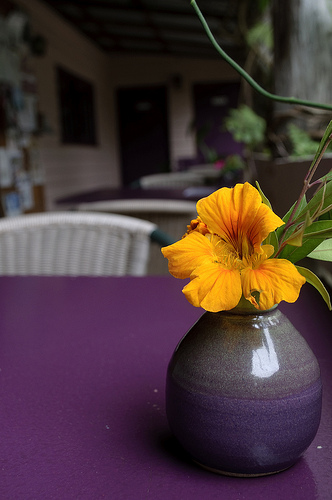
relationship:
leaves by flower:
[255, 119, 330, 311] [162, 180, 306, 309]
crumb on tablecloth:
[151, 386, 161, 394] [1, 268, 330, 497]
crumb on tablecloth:
[314, 442, 322, 449] [1, 268, 330, 497]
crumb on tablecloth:
[103, 423, 109, 430] [1, 268, 330, 497]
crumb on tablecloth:
[156, 406, 162, 411] [1, 268, 330, 497]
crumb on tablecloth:
[152, 399, 159, 409] [1, 268, 330, 497]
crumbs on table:
[151, 387, 159, 411] [10, 275, 165, 488]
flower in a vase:
[162, 180, 306, 309] [155, 312, 320, 475]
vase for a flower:
[162, 296, 327, 478] [162, 180, 306, 309]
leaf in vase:
[256, 171, 332, 266] [162, 296, 327, 478]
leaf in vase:
[280, 219, 330, 267] [162, 296, 327, 478]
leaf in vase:
[288, 262, 330, 311] [162, 296, 327, 478]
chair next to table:
[1, 207, 155, 274] [2, 271, 324, 499]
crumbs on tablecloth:
[151, 387, 164, 421] [1, 268, 330, 497]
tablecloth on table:
[55, 184, 210, 215] [64, 187, 213, 208]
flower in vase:
[162, 180, 306, 309] [162, 296, 327, 478]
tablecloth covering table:
[1, 268, 330, 497] [2, 271, 324, 499]